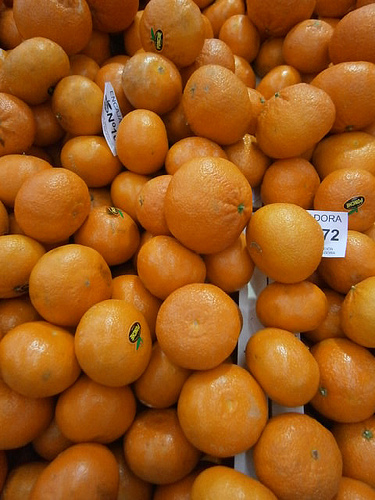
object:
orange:
[182, 64, 250, 147]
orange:
[255, 83, 335, 158]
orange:
[13, 167, 91, 240]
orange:
[166, 157, 253, 254]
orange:
[314, 167, 375, 232]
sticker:
[153, 30, 164, 53]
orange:
[140, 1, 204, 69]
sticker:
[344, 195, 365, 210]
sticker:
[128, 320, 142, 343]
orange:
[74, 298, 152, 387]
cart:
[1, 1, 374, 500]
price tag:
[101, 81, 124, 159]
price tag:
[307, 209, 348, 258]